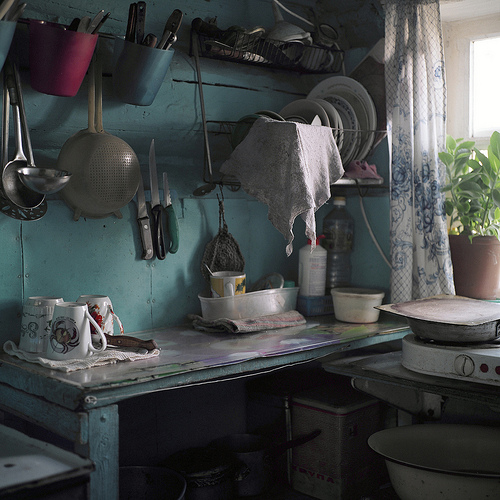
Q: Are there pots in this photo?
A: Yes, there is a pot.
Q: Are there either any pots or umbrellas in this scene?
A: Yes, there is a pot.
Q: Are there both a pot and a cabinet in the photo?
A: No, there is a pot but no cabinets.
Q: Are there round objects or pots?
A: Yes, there is a round pot.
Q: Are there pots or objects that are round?
A: Yes, the pot is round.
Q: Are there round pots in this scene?
A: Yes, there is a round pot.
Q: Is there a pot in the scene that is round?
A: Yes, there is a pot that is round.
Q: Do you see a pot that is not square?
A: Yes, there is a round pot.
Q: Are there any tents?
A: No, there are no tents.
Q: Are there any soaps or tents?
A: No, there are no tents or soaps.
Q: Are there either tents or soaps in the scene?
A: No, there are no tents or soaps.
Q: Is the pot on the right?
A: Yes, the pot is on the right of the image.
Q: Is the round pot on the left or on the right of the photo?
A: The pot is on the right of the image.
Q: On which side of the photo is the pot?
A: The pot is on the right of the image.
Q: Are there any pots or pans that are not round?
A: No, there is a pot but it is round.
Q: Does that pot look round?
A: Yes, the pot is round.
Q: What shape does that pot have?
A: The pot has round shape.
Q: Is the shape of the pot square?
A: No, the pot is round.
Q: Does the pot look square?
A: No, the pot is round.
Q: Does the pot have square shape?
A: No, the pot is round.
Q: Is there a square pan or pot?
A: No, there is a pot but it is round.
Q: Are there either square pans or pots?
A: No, there is a pot but it is round.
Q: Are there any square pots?
A: No, there is a pot but it is round.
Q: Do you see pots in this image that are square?
A: No, there is a pot but it is round.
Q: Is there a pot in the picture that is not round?
A: No, there is a pot but it is round.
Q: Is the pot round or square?
A: The pot is round.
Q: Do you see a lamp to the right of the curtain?
A: No, there is a pot to the right of the curtain.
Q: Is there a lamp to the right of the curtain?
A: No, there is a pot to the right of the curtain.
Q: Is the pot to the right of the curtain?
A: Yes, the pot is to the right of the curtain.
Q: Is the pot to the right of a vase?
A: No, the pot is to the right of the curtain.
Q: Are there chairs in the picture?
A: No, there are no chairs.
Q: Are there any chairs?
A: No, there are no chairs.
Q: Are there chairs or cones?
A: No, there are no chairs or cones.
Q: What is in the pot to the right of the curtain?
A: The plant is in the pot.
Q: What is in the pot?
A: The plant is in the pot.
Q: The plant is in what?
A: The plant is in the pot.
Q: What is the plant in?
A: The plant is in the pot.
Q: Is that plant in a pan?
A: No, the plant is in the pot.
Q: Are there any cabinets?
A: No, there are no cabinets.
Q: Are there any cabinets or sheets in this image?
A: No, there are no cabinets or sheets.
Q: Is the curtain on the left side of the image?
A: No, the curtain is on the right of the image.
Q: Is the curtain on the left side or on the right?
A: The curtain is on the right of the image.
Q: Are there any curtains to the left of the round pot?
A: Yes, there is a curtain to the left of the pot.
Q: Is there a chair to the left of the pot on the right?
A: No, there is a curtain to the left of the pot.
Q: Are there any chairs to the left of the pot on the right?
A: No, there is a curtain to the left of the pot.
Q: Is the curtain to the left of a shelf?
A: No, the curtain is to the left of a pot.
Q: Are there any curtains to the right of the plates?
A: Yes, there is a curtain to the right of the plates.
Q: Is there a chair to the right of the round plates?
A: No, there is a curtain to the right of the plates.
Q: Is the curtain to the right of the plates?
A: Yes, the curtain is to the right of the plates.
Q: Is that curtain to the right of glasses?
A: No, the curtain is to the right of the plates.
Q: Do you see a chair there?
A: No, there are no chairs.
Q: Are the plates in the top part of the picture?
A: Yes, the plates are in the top of the image.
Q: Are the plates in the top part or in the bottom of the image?
A: The plates are in the top of the image.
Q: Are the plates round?
A: Yes, the plates are round.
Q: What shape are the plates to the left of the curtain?
A: The plates are round.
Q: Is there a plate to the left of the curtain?
A: Yes, there are plates to the left of the curtain.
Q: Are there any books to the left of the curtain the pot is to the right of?
A: No, there are plates to the left of the curtain.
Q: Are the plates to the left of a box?
A: No, the plates are to the left of the curtain.